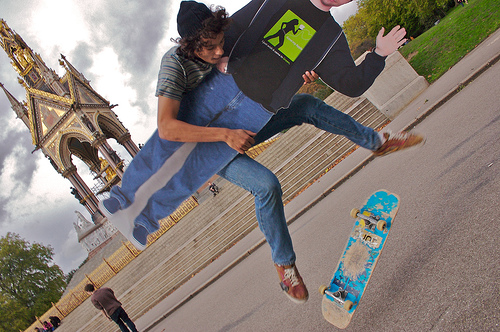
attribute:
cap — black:
[172, 0, 221, 29]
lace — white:
[284, 266, 304, 288]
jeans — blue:
[102, 70, 270, 225]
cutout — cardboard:
[96, 1, 409, 245]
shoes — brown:
[373, 130, 421, 152]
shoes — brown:
[274, 257, 313, 303]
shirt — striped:
[153, 44, 218, 99]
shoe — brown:
[267, 261, 307, 305]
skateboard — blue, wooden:
[314, 185, 400, 330]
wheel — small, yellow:
[347, 206, 365, 224]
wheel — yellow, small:
[373, 217, 390, 230]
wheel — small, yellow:
[340, 297, 353, 313]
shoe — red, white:
[375, 129, 424, 159]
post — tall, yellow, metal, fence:
[33, 313, 49, 327]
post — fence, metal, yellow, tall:
[83, 272, 95, 292]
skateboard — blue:
[311, 186, 408, 317]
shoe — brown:
[272, 257, 311, 302]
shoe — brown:
[370, 125, 426, 155]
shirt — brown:
[89, 285, 120, 312]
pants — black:
[113, 311, 135, 326]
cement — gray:
[83, 43, 479, 323]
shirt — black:
[215, 6, 385, 117]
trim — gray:
[354, 223, 379, 245]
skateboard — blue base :
[324, 194, 396, 305]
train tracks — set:
[200, 300, 270, 330]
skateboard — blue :
[293, 187, 421, 327]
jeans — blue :
[164, 111, 379, 297]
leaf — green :
[414, 18, 472, 108]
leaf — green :
[23, 249, 39, 279]